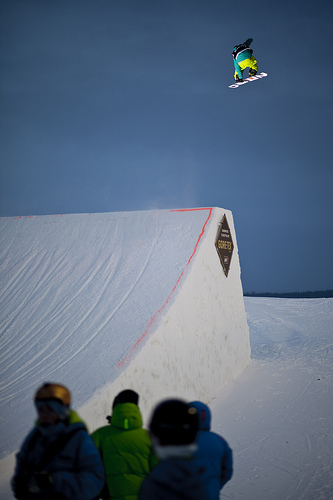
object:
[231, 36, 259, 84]
person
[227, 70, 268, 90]
snowboard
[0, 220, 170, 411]
tracks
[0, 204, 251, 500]
pike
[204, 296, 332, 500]
snow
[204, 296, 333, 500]
ground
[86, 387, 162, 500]
person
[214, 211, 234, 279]
sign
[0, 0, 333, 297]
sky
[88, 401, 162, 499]
coat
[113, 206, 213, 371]
marking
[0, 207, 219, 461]
ramp